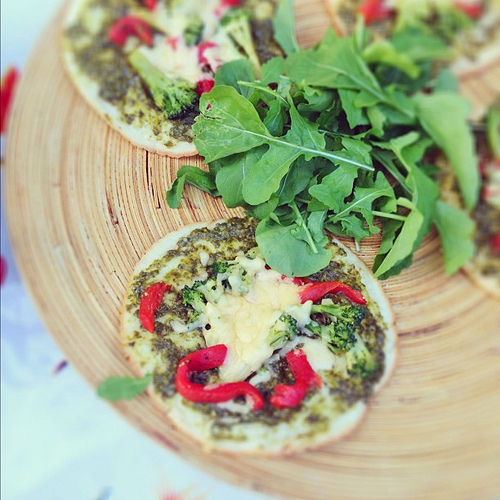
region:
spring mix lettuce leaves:
[179, 40, 461, 275]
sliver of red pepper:
[175, 348, 262, 414]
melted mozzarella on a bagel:
[183, 259, 320, 408]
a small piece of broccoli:
[278, 288, 360, 359]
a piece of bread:
[118, 213, 402, 451]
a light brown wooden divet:
[15, 0, 496, 494]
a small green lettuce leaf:
[95, 372, 155, 397]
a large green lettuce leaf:
[194, 77, 374, 207]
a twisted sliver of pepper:
[300, 270, 367, 312]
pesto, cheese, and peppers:
[119, 213, 397, 445]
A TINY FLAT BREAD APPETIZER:
[123, 215, 400, 449]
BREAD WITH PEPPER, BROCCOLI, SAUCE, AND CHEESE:
[119, 212, 399, 457]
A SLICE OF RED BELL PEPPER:
[174, 344, 264, 410]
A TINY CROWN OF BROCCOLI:
[293, 303, 362, 353]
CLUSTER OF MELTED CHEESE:
[191, 256, 311, 384]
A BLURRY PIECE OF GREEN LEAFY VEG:
[93, 371, 153, 401]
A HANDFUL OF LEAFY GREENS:
[194, 41, 481, 274]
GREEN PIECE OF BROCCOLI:
[127, 50, 201, 121]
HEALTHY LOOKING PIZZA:
[62, 0, 292, 158]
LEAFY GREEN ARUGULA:
[196, 87, 378, 204]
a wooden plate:
[19, 97, 480, 499]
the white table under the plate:
[18, 376, 111, 464]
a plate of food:
[39, 15, 468, 405]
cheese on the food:
[219, 296, 264, 348]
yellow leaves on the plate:
[220, 105, 443, 220]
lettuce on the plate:
[211, 35, 463, 229]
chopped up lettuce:
[241, 145, 474, 269]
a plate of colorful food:
[69, 0, 498, 425]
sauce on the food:
[141, 334, 176, 365]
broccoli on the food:
[129, 48, 188, 112]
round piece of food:
[106, 193, 413, 459]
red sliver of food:
[161, 339, 266, 411]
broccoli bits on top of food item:
[177, 254, 233, 316]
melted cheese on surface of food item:
[181, 247, 295, 392]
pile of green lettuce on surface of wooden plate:
[161, 28, 486, 289]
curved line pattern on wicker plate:
[31, 142, 116, 248]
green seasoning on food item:
[205, 217, 250, 248]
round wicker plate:
[7, 3, 494, 497]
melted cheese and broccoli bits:
[259, 302, 316, 349]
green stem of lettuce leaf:
[297, 228, 327, 256]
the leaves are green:
[204, 57, 461, 227]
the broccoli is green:
[306, 303, 364, 349]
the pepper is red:
[179, 341, 264, 408]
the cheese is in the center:
[195, 273, 312, 357]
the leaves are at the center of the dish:
[13, 0, 499, 443]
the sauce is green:
[191, 219, 254, 250]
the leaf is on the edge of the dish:
[93, 222, 380, 449]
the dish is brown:
[13, 50, 498, 496]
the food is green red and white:
[116, 212, 392, 448]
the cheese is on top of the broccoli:
[191, 281, 359, 358]